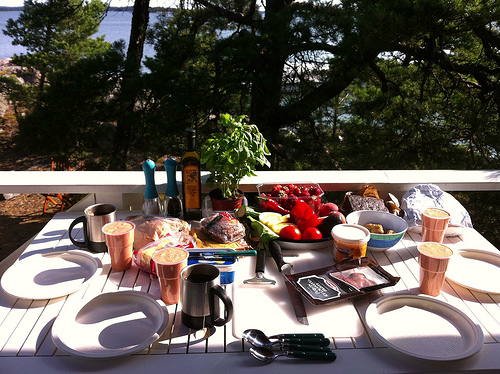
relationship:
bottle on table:
[182, 119, 204, 214] [0, 207, 495, 367]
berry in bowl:
[309, 184, 323, 196] [258, 182, 325, 212]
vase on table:
[210, 184, 248, 216] [0, 207, 495, 367]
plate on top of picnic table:
[51, 289, 168, 359] [0, 212, 500, 373]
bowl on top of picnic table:
[364, 293, 485, 363] [0, 212, 500, 373]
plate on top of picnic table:
[1, 250, 101, 300] [0, 212, 500, 373]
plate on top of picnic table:
[440, 246, 499, 291] [0, 212, 500, 373]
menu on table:
[283, 256, 399, 306] [0, 207, 495, 367]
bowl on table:
[353, 290, 473, 363] [40, 187, 450, 364]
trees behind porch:
[3, 6, 495, 166] [10, 126, 486, 371]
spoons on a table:
[247, 324, 330, 367] [148, 353, 213, 368]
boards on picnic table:
[1, 314, 48, 352] [137, 189, 294, 338]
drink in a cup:
[153, 247, 186, 272] [153, 246, 187, 301]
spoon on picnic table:
[245, 330, 330, 352] [0, 212, 500, 373]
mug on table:
[66, 200, 120, 251] [0, 207, 495, 367]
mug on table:
[178, 261, 233, 329] [0, 207, 495, 367]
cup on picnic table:
[101, 219, 134, 269] [0, 212, 500, 373]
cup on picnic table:
[154, 245, 190, 304] [0, 212, 500, 373]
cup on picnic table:
[414, 238, 451, 293] [0, 212, 500, 373]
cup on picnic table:
[417, 204, 448, 240] [0, 212, 500, 373]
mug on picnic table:
[178, 261, 233, 329] [0, 212, 500, 373]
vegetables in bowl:
[262, 182, 342, 236] [243, 185, 354, 247]